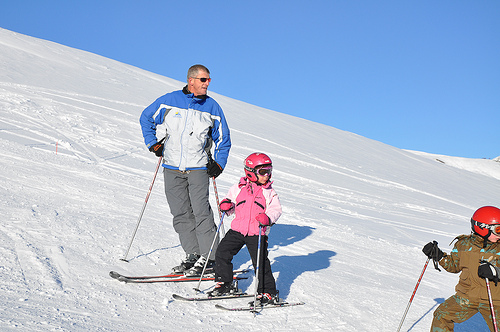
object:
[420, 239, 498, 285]
gloves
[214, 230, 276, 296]
pants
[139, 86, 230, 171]
jacket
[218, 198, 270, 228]
gloves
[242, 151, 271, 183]
helmet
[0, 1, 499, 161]
sky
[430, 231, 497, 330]
ski suit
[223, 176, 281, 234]
ski jacket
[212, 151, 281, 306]
girl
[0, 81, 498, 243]
tracks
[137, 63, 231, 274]
man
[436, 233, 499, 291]
coat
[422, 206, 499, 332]
boy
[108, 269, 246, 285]
skis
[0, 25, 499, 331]
mountain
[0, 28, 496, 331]
ground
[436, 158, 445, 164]
rocks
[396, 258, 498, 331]
pole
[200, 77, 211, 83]
goggles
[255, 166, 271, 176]
sunglasses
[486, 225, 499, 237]
goggles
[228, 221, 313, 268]
shadow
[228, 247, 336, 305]
shadow